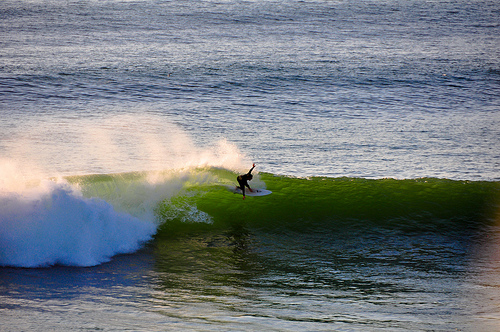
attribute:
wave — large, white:
[0, 170, 498, 270]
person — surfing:
[230, 159, 261, 199]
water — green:
[73, 155, 453, 226]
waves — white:
[26, 123, 224, 261]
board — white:
[215, 180, 292, 219]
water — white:
[7, 170, 150, 264]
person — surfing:
[226, 159, 269, 180]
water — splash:
[51, 134, 224, 264]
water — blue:
[99, 35, 494, 160]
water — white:
[15, 140, 200, 290]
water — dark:
[36, 259, 352, 329]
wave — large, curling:
[13, 156, 173, 261]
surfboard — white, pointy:
[214, 189, 276, 212]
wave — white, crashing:
[5, 158, 164, 253]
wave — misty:
[29, 137, 194, 250]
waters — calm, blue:
[34, 82, 388, 307]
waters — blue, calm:
[28, 8, 497, 196]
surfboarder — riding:
[214, 158, 289, 212]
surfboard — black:
[227, 183, 275, 203]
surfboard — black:
[218, 177, 262, 201]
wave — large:
[1, 165, 219, 293]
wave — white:
[32, 138, 201, 290]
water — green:
[118, 219, 383, 300]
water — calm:
[303, 47, 445, 150]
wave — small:
[63, 159, 192, 210]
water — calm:
[21, 236, 168, 328]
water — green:
[23, 206, 171, 282]